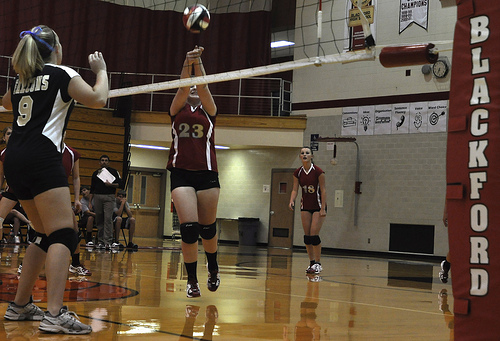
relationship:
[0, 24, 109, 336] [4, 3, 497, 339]
female in a basketball game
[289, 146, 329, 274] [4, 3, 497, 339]
female in a basketball game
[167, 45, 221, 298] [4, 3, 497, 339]
female in a basketball game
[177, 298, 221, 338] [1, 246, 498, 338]
shadow in on floor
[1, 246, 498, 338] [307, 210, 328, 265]
floor of leg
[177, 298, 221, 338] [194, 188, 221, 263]
shadow of leg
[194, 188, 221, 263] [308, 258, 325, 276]
leg and sneaker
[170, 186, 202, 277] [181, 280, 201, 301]
leg and sneaker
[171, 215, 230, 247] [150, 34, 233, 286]
knee pads on player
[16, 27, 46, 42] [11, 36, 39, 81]
ribbon in hair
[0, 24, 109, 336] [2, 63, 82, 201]
female in uniform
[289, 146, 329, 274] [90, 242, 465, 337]
female standing on court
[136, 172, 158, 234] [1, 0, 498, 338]
door to gym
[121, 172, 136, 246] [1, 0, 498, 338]
door to gym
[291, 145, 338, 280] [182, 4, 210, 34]
female playing ball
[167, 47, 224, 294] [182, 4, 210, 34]
female playing ball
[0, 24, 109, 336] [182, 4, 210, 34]
female playing ball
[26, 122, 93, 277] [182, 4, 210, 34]
female playing ball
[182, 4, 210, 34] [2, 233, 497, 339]
ball on court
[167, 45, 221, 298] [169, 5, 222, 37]
female hitting ball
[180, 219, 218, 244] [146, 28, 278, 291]
knee pads on player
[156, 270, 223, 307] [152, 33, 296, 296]
sneakers on player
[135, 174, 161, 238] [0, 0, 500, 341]
door on blackford gym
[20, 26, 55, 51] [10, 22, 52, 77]
ribbon in hair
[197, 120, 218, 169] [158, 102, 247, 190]
stripe on shirt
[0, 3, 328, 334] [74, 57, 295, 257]
basketball game at blackford gym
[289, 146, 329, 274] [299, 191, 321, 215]
female in shorts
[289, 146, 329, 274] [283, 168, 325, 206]
female in top